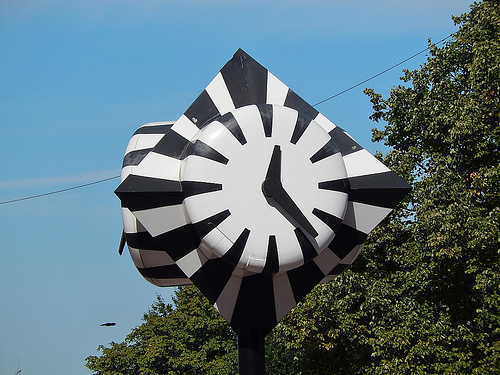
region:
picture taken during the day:
[39, 24, 296, 336]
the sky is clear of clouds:
[31, 38, 124, 168]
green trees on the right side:
[401, 110, 465, 366]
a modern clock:
[112, 69, 474, 330]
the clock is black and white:
[86, 28, 403, 370]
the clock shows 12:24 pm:
[168, 114, 390, 317]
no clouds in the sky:
[43, 31, 149, 111]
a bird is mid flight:
[73, 284, 143, 344]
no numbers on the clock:
[173, 104, 420, 369]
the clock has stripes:
[71, 60, 463, 326]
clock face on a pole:
[200, 101, 351, 282]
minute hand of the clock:
[261, 180, 321, 250]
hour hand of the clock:
[255, 130, 295, 205]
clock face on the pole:
[147, 100, 397, 285]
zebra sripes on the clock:
[131, 110, 246, 255]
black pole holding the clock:
[230, 330, 290, 365]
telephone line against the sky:
[10, 140, 110, 240]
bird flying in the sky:
[77, 311, 127, 348]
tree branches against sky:
[331, 90, 428, 156]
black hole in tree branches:
[415, 240, 475, 372]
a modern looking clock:
[179, 103, 353, 263]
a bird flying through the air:
[95, 317, 120, 329]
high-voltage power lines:
[6, 187, 62, 207]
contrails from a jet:
[1, 170, 79, 187]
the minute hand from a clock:
[266, 185, 318, 237]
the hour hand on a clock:
[257, 143, 294, 201]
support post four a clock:
[229, 330, 268, 374]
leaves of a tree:
[413, 75, 498, 315]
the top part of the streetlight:
[11, 362, 22, 372]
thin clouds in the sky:
[272, 0, 444, 41]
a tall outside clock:
[97, 45, 439, 370]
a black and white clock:
[115, 34, 451, 354]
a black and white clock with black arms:
[46, 13, 412, 345]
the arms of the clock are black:
[91, 31, 423, 327]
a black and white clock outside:
[71, 29, 449, 353]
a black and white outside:
[26, 20, 416, 373]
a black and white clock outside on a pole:
[37, 9, 400, 374]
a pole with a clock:
[15, 29, 357, 373]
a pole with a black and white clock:
[54, 27, 379, 371]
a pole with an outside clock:
[93, 24, 419, 371]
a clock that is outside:
[67, 37, 327, 373]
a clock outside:
[84, 43, 454, 371]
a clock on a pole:
[122, 57, 379, 369]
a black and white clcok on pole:
[91, 31, 422, 371]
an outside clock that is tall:
[80, 22, 428, 357]